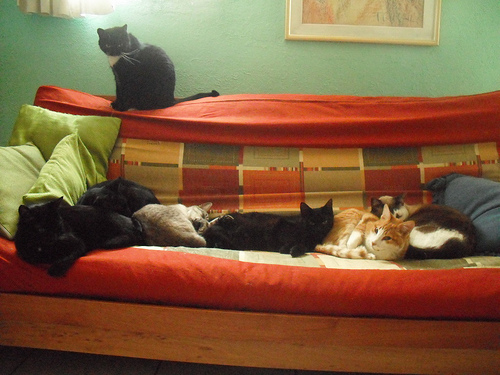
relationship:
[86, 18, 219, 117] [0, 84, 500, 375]
cat sitting on sofa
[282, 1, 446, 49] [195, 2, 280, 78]
picture on wall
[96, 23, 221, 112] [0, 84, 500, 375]
cat on sofa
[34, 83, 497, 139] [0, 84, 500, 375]
cover on back of sofa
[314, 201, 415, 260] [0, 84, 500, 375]
cat laying down on sofa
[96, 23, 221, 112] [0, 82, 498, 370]
cat on sofa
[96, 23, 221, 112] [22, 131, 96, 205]
cat next to pillow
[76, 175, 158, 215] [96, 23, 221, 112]
cat resting on cat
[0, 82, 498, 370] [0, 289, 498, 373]
sofa has wood frame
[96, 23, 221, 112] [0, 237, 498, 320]
cat on futon cushion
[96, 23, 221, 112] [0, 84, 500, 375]
cat laying on sofa